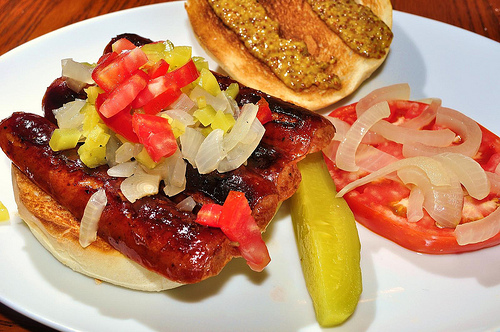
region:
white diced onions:
[190, 129, 253, 164]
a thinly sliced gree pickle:
[299, 171, 368, 322]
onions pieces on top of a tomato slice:
[368, 111, 472, 207]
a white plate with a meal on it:
[209, 300, 292, 329]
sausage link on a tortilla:
[19, 124, 46, 186]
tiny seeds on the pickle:
[334, 252, 346, 291]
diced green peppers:
[59, 119, 102, 163]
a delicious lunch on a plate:
[11, 8, 494, 311]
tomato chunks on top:
[104, 62, 158, 113]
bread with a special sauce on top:
[234, 6, 381, 86]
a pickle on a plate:
[266, 120, 351, 327]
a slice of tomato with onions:
[303, 80, 466, 264]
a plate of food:
[1, 17, 474, 317]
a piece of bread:
[18, 132, 150, 308]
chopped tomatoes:
[80, 44, 194, 161]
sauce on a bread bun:
[158, 2, 426, 94]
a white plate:
[0, 20, 475, 238]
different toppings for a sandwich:
[31, 57, 296, 219]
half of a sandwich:
[38, 78, 347, 327]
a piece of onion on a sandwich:
[68, 181, 115, 249]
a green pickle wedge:
[280, 142, 366, 330]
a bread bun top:
[182, 0, 405, 121]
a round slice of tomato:
[329, 97, 499, 257]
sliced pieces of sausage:
[0, 77, 316, 238]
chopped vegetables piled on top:
[59, 37, 261, 179]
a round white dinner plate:
[3, 12, 498, 329]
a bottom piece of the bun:
[9, 173, 168, 293]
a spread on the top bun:
[215, 0, 334, 83]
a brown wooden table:
[0, 0, 153, 59]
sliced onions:
[359, 96, 473, 209]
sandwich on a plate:
[29, 14, 484, 295]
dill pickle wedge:
[278, 134, 383, 322]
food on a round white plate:
[8, 3, 243, 275]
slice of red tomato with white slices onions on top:
[337, 80, 484, 259]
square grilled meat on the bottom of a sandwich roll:
[0, 66, 280, 285]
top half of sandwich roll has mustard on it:
[187, 1, 398, 86]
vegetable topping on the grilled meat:
[40, 18, 260, 179]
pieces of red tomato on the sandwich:
[92, 37, 184, 164]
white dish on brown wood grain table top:
[12, 3, 84, 45]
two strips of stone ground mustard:
[193, 9, 426, 79]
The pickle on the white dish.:
[299, 158, 362, 321]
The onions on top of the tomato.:
[342, 85, 496, 233]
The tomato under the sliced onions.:
[326, 99, 499, 254]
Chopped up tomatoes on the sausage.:
[94, 51, 198, 168]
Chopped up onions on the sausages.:
[54, 103, 267, 236]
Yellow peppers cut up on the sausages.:
[38, 53, 240, 165]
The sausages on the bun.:
[8, 57, 319, 279]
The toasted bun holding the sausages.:
[13, 172, 201, 288]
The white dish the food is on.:
[6, 18, 493, 330]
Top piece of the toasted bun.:
[183, 1, 393, 108]